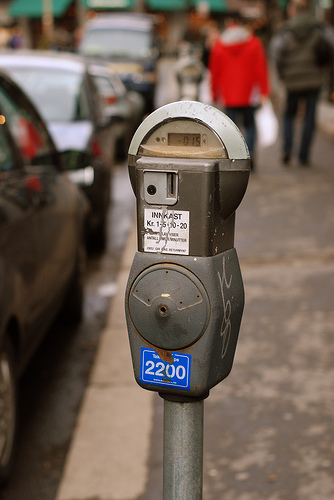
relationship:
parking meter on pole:
[68, 57, 294, 455] [141, 382, 237, 495]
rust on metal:
[140, 337, 184, 363] [152, 402, 242, 454]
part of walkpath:
[254, 162, 330, 496] [259, 144, 331, 499]